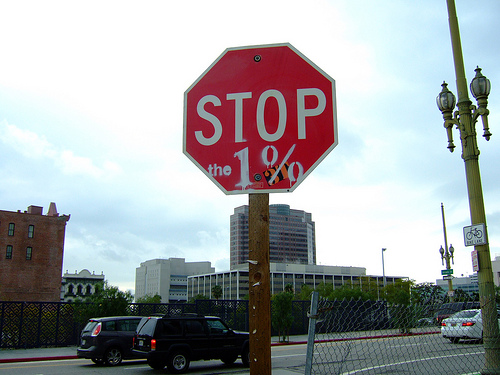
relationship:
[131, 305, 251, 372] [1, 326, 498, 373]
jeep on road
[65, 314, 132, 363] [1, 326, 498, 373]
suv on road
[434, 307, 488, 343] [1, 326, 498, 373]
car on road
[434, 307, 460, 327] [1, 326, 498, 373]
car on road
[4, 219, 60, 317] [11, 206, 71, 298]
wall on building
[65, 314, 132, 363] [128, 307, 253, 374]
suv side vehicles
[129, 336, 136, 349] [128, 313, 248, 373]
light on vehicle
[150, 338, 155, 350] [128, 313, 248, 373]
light on vehicle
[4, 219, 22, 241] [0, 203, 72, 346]
window on building